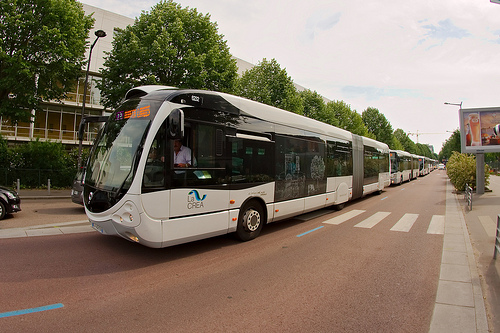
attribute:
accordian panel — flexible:
[349, 130, 364, 203]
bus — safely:
[122, 94, 342, 214]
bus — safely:
[392, 145, 419, 175]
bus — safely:
[417, 153, 441, 170]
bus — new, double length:
[77, 80, 393, 253]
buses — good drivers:
[29, 15, 442, 282]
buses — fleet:
[21, 9, 488, 328]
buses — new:
[75, 77, 440, 267]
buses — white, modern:
[80, 81, 437, 250]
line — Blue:
[2, 296, 83, 316]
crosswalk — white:
[321, 198, 447, 236]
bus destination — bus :
[111, 105, 153, 123]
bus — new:
[387, 146, 424, 184]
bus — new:
[421, 150, 442, 174]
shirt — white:
[168, 145, 198, 171]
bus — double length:
[387, 146, 419, 186]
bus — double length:
[415, 154, 431, 176]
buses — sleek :
[79, 84, 393, 249]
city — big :
[2, 2, 497, 329]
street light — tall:
[80, 27, 106, 124]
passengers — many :
[235, 118, 430, 178]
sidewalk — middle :
[420, 194, 473, 326]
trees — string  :
[5, 4, 441, 199]